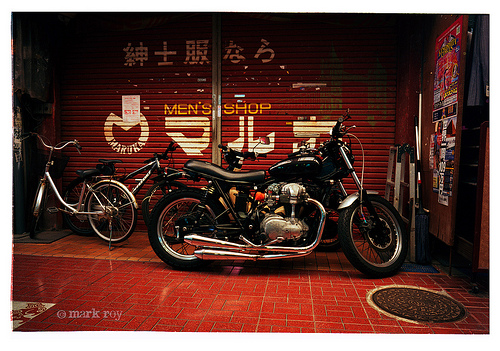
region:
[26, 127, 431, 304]
Two bicycles and a motorcycle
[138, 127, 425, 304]
A black and chrome motorcycle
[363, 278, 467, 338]
Man hole cover on ground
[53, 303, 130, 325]
Photographer's name in white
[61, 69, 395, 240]
A red door with white writing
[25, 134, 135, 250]
A silver bicycle with black seat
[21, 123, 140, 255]
A silver bicycle behind motorcycle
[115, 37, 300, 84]
Chinese writing on wall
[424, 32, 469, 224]
Lots of pictures on the wall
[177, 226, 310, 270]
Chrome muffler of motorcycle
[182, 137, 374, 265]
black and silver motorcycle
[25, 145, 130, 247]
black and silver bicycle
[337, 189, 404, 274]
black and silver tire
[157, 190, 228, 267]
black and silver tire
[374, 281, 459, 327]
brown manhole cover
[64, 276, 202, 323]
shiny red bricks on ground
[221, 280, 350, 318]
shiny red bricks on ground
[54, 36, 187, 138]
red white and yellow sign on wall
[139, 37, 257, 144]
red white and yellow sign on wall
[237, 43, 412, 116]
red white and yellow sign on wall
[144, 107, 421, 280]
The motorcycle is black.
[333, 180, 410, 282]
Motorcycle has front tire.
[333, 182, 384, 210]
Front fender is silver.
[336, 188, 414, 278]
Front tire is round.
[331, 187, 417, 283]
Front tire is black.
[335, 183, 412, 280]
Front tire is inflated.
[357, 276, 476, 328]
Manhole cover is round.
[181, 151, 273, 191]
Motorcycle seat is black.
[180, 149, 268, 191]
Motorcycle seat is leather.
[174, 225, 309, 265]
Motorcycle exhaust is chrome.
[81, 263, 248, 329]
red ceramic tiled flooring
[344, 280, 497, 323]
manhole covering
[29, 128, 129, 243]
bicycle parked on the red floor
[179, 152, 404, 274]
motorcycle parked in a garage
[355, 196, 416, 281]
front wheel of the motorcycle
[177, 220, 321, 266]
exhaust pipes on the motorcycle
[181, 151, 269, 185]
motorcycle seat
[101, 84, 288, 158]
advertising on the garage door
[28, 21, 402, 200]
Red garage door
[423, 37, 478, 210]
Advertising on the wall in the garage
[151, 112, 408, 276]
a black motorcycle in front of a red door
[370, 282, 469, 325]
metal manhole cover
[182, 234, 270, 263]
metal exhaust pipes on a motorcycle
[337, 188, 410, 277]
front wheel of a motorcycle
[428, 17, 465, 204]
posters and stickers on a wall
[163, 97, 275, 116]
yellow lettering reading "men's shop"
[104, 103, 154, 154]
white symbol on red metal door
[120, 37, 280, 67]
white foreign symbols on a red metal door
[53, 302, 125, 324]
mark roy watermark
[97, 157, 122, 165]
the seat of a bicycle